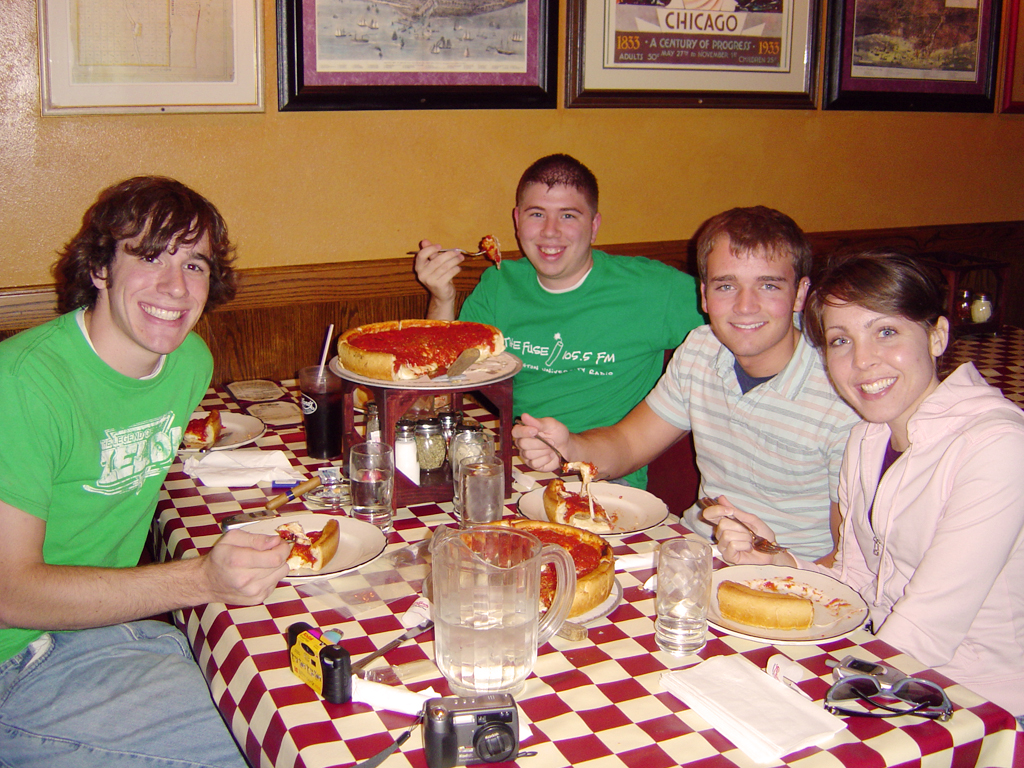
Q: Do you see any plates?
A: Yes, there is a plate.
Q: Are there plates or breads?
A: Yes, there is a plate.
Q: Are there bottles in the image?
A: No, there are no bottles.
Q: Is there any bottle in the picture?
A: No, there are no bottles.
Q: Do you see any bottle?
A: No, there are no bottles.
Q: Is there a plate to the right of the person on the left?
A: Yes, there is a plate to the right of the person.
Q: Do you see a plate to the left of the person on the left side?
A: No, the plate is to the right of the person.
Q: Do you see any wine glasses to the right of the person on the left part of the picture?
A: No, there is a plate to the right of the person.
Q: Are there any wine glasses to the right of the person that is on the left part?
A: No, there is a plate to the right of the person.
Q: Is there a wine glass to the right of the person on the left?
A: No, there is a plate to the right of the person.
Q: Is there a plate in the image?
A: Yes, there is a plate.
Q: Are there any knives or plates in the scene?
A: Yes, there is a plate.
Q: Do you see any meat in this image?
A: No, there is no meat.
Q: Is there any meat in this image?
A: No, there is no meat.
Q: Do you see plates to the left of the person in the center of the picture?
A: Yes, there is a plate to the left of the person.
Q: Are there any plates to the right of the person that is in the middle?
A: No, the plate is to the left of the person.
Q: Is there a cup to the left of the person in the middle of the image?
A: No, there is a plate to the left of the person.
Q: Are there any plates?
A: Yes, there is a plate.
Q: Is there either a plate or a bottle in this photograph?
A: Yes, there is a plate.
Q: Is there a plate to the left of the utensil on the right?
A: Yes, there is a plate to the left of the utensil.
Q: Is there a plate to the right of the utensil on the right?
A: No, the plate is to the left of the utensil.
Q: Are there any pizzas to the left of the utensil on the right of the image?
A: No, there is a plate to the left of the utensil.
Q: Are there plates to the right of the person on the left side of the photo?
A: Yes, there is a plate to the right of the person.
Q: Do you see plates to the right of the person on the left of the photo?
A: Yes, there is a plate to the right of the person.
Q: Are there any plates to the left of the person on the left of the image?
A: No, the plate is to the right of the person.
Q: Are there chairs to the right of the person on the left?
A: No, there is a plate to the right of the person.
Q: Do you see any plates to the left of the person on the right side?
A: Yes, there is a plate to the left of the person.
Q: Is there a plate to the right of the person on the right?
A: No, the plate is to the left of the person.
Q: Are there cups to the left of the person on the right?
A: No, there is a plate to the left of the person.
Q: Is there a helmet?
A: No, there are no helmets.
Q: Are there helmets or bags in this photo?
A: No, there are no helmets or bags.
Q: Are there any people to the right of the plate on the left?
A: Yes, there is a person to the right of the plate.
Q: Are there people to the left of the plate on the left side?
A: No, the person is to the right of the plate.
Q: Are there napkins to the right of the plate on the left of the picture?
A: No, there is a person to the right of the plate.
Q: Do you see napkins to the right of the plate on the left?
A: No, there is a person to the right of the plate.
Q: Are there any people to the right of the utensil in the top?
A: Yes, there is a person to the right of the utensil.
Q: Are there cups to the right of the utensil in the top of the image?
A: No, there is a person to the right of the utensil.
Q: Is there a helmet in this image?
A: No, there are no helmets.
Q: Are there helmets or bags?
A: No, there are no helmets or bags.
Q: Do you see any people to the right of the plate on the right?
A: Yes, there is a person to the right of the plate.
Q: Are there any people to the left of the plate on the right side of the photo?
A: No, the person is to the right of the plate.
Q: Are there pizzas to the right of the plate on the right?
A: No, there is a person to the right of the plate.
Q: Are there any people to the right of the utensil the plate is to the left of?
A: Yes, there is a person to the right of the utensil.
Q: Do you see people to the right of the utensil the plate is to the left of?
A: Yes, there is a person to the right of the utensil.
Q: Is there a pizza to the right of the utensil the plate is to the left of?
A: No, there is a person to the right of the utensil.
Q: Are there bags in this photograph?
A: No, there are no bags.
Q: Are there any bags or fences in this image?
A: No, there are no bags or fences.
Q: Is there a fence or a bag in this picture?
A: No, there are no bags or fences.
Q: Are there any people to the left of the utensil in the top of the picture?
A: Yes, there is a person to the left of the utensil.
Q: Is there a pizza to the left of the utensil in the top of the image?
A: No, there is a person to the left of the utensil.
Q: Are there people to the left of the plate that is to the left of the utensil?
A: Yes, there is a person to the left of the plate.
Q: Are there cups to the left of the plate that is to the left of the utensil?
A: No, there is a person to the left of the plate.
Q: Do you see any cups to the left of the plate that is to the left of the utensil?
A: No, there is a person to the left of the plate.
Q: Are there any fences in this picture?
A: No, there are no fences.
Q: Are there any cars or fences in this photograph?
A: No, there are no fences or cars.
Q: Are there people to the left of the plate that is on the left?
A: No, the person is to the right of the plate.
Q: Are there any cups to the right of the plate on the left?
A: No, there is a person to the right of the plate.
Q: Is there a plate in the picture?
A: Yes, there is a plate.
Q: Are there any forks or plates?
A: Yes, there is a plate.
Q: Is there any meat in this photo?
A: No, there is no meat.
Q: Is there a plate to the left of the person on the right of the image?
A: Yes, there is a plate to the left of the person.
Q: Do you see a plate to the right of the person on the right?
A: No, the plate is to the left of the person.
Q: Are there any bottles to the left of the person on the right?
A: No, there is a plate to the left of the person.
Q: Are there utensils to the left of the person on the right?
A: Yes, there is a utensil to the left of the person.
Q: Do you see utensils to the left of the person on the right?
A: Yes, there is a utensil to the left of the person.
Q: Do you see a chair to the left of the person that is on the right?
A: No, there is a utensil to the left of the person.